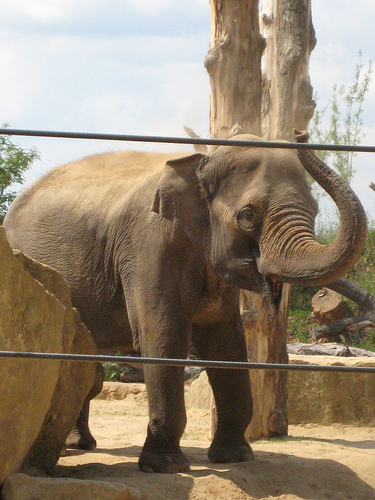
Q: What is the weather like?
A: It is cloudy.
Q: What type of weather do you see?
A: It is cloudy.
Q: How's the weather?
A: It is cloudy.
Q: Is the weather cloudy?
A: Yes, it is cloudy.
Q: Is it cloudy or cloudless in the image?
A: It is cloudy.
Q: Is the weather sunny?
A: No, it is cloudy.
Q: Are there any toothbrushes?
A: No, there are no toothbrushes.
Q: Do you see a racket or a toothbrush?
A: No, there are no toothbrushes or rackets.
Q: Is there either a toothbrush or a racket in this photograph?
A: No, there are no toothbrushes or rackets.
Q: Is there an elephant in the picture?
A: Yes, there is an elephant.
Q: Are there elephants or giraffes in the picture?
A: Yes, there is an elephant.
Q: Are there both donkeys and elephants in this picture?
A: No, there is an elephant but no donkeys.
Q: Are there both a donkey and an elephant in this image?
A: No, there is an elephant but no donkeys.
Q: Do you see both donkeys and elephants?
A: No, there is an elephant but no donkeys.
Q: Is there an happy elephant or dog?
A: Yes, there is a happy elephant.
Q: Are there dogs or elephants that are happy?
A: Yes, the elephant is happy.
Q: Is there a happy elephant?
A: Yes, there is a happy elephant.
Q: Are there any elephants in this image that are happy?
A: Yes, there is an elephant that is happy.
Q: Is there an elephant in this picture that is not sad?
A: Yes, there is a happy elephant.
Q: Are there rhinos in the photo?
A: No, there are no rhinos.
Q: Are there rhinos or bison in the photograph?
A: No, there are no rhinos or bison.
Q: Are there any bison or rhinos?
A: No, there are no rhinos or bison.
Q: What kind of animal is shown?
A: The animal is an elephant.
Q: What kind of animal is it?
A: The animal is an elephant.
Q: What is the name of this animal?
A: This is an elephant.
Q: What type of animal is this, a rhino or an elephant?
A: This is an elephant.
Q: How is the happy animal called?
A: The animal is an elephant.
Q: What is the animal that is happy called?
A: The animal is an elephant.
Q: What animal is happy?
A: The animal is an elephant.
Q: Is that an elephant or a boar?
A: That is an elephant.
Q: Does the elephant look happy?
A: Yes, the elephant is happy.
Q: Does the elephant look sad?
A: No, the elephant is happy.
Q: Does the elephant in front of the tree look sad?
A: No, the elephant is happy.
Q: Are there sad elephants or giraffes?
A: No, there is an elephant but it is happy.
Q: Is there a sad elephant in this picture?
A: No, there is an elephant but it is happy.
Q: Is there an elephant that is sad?
A: No, there is an elephant but it is happy.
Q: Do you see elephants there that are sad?
A: No, there is an elephant but it is happy.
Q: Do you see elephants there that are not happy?
A: No, there is an elephant but it is happy.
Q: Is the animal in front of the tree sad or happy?
A: The elephant is happy.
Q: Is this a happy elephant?
A: Yes, this is a happy elephant.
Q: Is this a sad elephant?
A: No, this is a happy elephant.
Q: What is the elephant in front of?
A: The elephant is in front of the tree.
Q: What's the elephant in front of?
A: The elephant is in front of the tree.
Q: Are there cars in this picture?
A: No, there are no cars.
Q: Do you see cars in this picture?
A: No, there are no cars.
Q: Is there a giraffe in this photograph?
A: No, there are no giraffes.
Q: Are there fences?
A: Yes, there is a fence.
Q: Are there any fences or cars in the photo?
A: Yes, there is a fence.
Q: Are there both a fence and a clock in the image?
A: No, there is a fence but no clocks.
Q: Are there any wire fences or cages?
A: Yes, there is a wire fence.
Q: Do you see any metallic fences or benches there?
A: Yes, there is a metal fence.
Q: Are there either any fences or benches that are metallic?
A: Yes, the fence is metallic.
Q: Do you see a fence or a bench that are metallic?
A: Yes, the fence is metallic.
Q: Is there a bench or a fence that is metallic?
A: Yes, the fence is metallic.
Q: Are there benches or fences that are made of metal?
A: Yes, the fence is made of metal.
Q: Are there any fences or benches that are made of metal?
A: Yes, the fence is made of metal.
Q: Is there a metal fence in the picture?
A: Yes, there is a metal fence.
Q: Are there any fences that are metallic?
A: Yes, there is a fence that is metallic.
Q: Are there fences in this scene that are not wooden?
A: Yes, there is a metallic fence.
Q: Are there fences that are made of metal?
A: Yes, there is a fence that is made of metal.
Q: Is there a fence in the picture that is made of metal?
A: Yes, there is a fence that is made of metal.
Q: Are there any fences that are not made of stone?
A: Yes, there is a fence that is made of metal.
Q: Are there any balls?
A: No, there are no balls.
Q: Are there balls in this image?
A: No, there are no balls.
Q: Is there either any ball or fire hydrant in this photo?
A: No, there are no balls or fire hydrants.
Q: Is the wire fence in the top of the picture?
A: Yes, the fence is in the top of the image.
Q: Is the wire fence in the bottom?
A: No, the fence is in the top of the image.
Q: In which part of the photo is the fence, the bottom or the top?
A: The fence is in the top of the image.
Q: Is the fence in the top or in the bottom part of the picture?
A: The fence is in the top of the image.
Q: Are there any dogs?
A: No, there are no dogs.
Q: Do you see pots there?
A: No, there are no pots.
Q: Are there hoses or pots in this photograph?
A: No, there are no pots or hoses.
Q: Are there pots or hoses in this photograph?
A: No, there are no pots or hoses.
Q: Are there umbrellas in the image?
A: No, there are no umbrellas.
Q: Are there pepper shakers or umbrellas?
A: No, there are no umbrellas or pepper shakers.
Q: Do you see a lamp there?
A: No, there are no lamps.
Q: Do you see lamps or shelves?
A: No, there are no lamps or shelves.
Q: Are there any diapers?
A: No, there are no diapers.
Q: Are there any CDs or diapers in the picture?
A: No, there are no diapers or cds.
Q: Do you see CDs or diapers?
A: No, there are no diapers or cds.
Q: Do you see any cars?
A: No, there are no cars.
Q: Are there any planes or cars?
A: No, there are no cars or planes.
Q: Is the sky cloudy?
A: Yes, the sky is cloudy.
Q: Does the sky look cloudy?
A: Yes, the sky is cloudy.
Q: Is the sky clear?
A: No, the sky is cloudy.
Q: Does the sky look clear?
A: No, the sky is cloudy.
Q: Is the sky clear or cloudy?
A: The sky is cloudy.